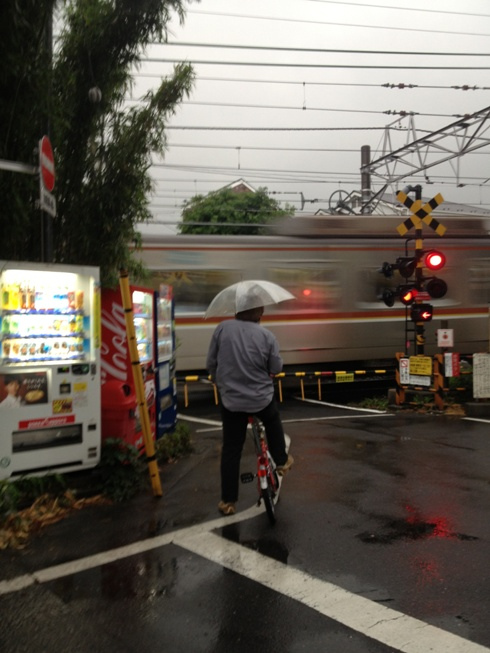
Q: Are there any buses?
A: No, there are no buses.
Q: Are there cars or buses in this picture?
A: No, there are no buses or cars.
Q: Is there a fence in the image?
A: No, there are no fences.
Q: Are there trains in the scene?
A: Yes, there is a train.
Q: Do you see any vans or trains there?
A: Yes, there is a train.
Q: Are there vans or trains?
A: Yes, there is a train.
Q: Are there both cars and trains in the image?
A: No, there is a train but no cars.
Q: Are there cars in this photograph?
A: No, there are no cars.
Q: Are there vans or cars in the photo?
A: No, there are no cars or vans.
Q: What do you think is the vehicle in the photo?
A: The vehicle is a train.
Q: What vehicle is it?
A: The vehicle is a train.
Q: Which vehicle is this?
A: This is a train.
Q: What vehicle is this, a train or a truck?
A: This is a train.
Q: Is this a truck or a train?
A: This is a train.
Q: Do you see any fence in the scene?
A: No, there are no fences.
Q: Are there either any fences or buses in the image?
A: No, there are no fences or buses.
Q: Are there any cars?
A: No, there are no cars.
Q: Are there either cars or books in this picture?
A: No, there are no cars or books.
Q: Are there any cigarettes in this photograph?
A: No, there are no cigarettes.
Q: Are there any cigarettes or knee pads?
A: No, there are no cigarettes or knee pads.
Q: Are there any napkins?
A: No, there are no napkins.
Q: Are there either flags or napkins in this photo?
A: No, there are no napkins or flags.